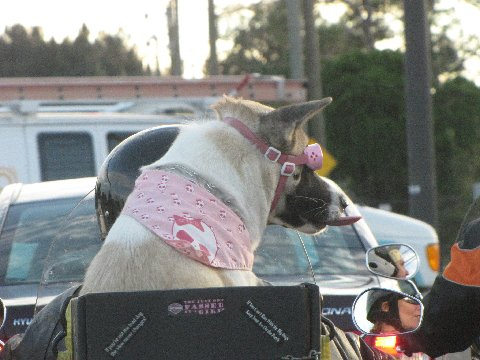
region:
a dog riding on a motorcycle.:
[74, 83, 379, 312]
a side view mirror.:
[335, 260, 435, 358]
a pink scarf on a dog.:
[123, 153, 269, 271]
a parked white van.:
[5, 62, 449, 311]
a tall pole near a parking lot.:
[402, 0, 436, 250]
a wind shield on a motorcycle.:
[75, 124, 390, 279]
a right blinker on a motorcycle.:
[363, 325, 410, 358]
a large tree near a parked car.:
[208, 8, 478, 247]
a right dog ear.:
[254, 91, 337, 161]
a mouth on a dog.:
[265, 169, 356, 254]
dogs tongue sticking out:
[332, 212, 365, 231]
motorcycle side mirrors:
[343, 240, 430, 340]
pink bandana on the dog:
[127, 169, 255, 271]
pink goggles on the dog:
[223, 116, 331, 204]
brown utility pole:
[398, 35, 439, 145]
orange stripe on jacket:
[446, 231, 478, 289]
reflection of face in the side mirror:
[356, 288, 428, 336]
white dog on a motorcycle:
[91, 76, 369, 294]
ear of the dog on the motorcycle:
[265, 92, 339, 135]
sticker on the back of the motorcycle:
[161, 299, 235, 321]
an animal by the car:
[48, 102, 349, 359]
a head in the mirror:
[364, 279, 429, 344]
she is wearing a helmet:
[361, 278, 404, 323]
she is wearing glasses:
[399, 293, 417, 306]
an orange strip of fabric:
[438, 231, 477, 283]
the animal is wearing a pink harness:
[209, 103, 335, 229]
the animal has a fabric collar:
[124, 154, 254, 282]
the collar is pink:
[134, 174, 264, 276]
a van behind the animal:
[10, 74, 332, 200]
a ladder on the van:
[0, 66, 314, 103]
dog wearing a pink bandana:
[122, 166, 255, 267]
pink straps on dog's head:
[222, 113, 309, 216]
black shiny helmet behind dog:
[94, 124, 187, 236]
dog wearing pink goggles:
[306, 141, 323, 169]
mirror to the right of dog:
[352, 286, 423, 335]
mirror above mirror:
[367, 243, 419, 278]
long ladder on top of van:
[1, 76, 307, 97]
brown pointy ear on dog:
[263, 94, 332, 147]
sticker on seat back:
[241, 299, 291, 342]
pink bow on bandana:
[173, 214, 203, 231]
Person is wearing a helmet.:
[100, 120, 211, 217]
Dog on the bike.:
[77, 94, 356, 297]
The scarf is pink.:
[132, 168, 260, 281]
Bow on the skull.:
[166, 208, 217, 237]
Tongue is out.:
[316, 197, 371, 239]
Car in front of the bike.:
[1, 176, 396, 311]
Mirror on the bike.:
[352, 283, 424, 339]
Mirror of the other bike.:
[367, 243, 422, 279]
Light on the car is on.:
[370, 332, 409, 355]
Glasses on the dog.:
[298, 135, 327, 176]